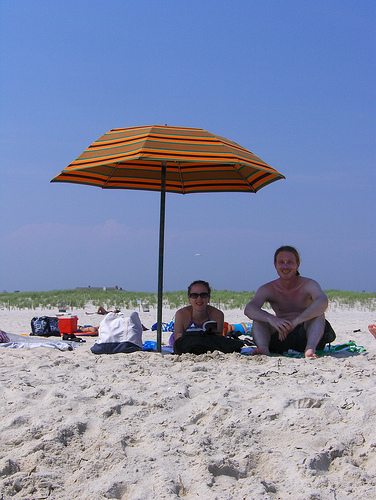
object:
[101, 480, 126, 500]
imprints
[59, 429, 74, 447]
imprint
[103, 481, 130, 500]
imprint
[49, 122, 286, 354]
umbrella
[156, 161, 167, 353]
pole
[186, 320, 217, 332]
book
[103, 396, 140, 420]
footstep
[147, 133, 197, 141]
stripes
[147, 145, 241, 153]
stripes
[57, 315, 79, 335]
cooler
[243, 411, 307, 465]
sand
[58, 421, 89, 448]
imprint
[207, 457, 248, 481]
imprint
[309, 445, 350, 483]
imprint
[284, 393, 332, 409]
imprint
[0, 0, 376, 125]
sky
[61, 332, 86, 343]
sandal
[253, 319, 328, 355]
shorts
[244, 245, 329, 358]
man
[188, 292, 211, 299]
sunglasses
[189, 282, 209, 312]
face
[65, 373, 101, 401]
sand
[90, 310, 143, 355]
bag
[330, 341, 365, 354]
green towel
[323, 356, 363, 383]
sand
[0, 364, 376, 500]
beach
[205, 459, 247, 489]
hole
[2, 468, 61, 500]
imprint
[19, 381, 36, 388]
imprint